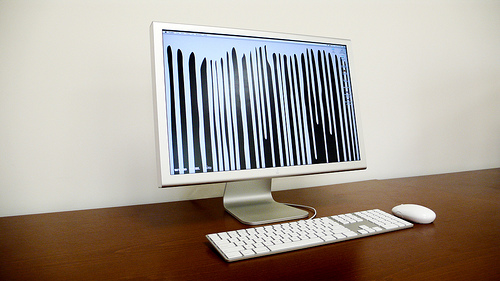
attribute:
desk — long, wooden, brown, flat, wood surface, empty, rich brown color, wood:
[0, 167, 499, 280]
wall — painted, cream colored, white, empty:
[1, 0, 500, 218]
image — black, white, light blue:
[163, 34, 361, 174]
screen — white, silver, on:
[149, 20, 366, 187]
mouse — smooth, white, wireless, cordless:
[392, 203, 437, 224]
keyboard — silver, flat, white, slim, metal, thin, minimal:
[205, 209, 414, 262]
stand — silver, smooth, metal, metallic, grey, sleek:
[223, 178, 310, 225]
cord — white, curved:
[282, 203, 317, 220]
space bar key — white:
[269, 237, 325, 253]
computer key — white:
[229, 236, 241, 244]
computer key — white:
[257, 232, 267, 239]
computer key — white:
[359, 229, 369, 235]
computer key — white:
[253, 246, 271, 255]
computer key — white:
[283, 229, 293, 234]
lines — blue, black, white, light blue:
[167, 45, 358, 175]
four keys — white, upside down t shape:
[358, 224, 382, 235]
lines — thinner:
[211, 58, 232, 170]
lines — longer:
[255, 45, 288, 169]